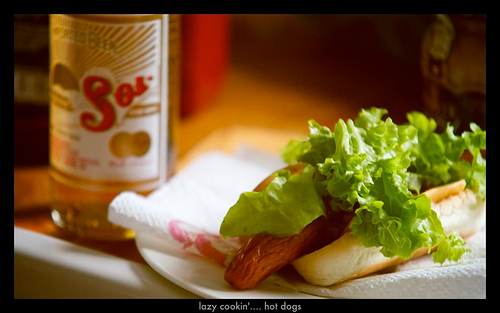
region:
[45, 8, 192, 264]
bottle made of glass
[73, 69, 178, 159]
red letters on bottle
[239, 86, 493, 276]
lettuce on the top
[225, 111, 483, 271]
the lettuce is green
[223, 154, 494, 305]
hot dog is inside bun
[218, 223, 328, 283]
hot dog is wrinkled up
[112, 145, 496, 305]
napkin under the bread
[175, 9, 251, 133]
red object behind glass bottle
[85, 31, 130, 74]
word beer is on bottle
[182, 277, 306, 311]
white letters on bottom of picture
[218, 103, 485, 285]
hot dog on a bun with lettuce on top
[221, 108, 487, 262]
green fresh lettuce on hot dog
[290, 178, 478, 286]
hot dog bun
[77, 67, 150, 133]
red symbol on on beer bottle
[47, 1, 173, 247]
bottle of beer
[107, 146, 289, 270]
white napkin under hot dog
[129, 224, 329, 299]
white plate for hot dog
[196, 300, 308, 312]
text on bottom of picture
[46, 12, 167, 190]
label on bottle of beer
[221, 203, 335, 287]
meat portion of hot dog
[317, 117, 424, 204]
The lettuce is green.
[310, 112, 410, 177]
Lettuce is on the hot dog.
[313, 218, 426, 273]
The hot dog is in a bun.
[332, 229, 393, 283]
The bun is white and brown.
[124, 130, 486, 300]
The food is on a plate.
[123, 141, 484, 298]
The plate is round.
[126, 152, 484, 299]
The plate is white.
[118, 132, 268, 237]
paper is on the plate.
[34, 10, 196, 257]
A bottle.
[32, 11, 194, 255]
The bottle is deer.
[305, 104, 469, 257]
lettuce on hot dog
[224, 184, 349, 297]
shriveled up hot dog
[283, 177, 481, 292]
short hot dog bun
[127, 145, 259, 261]
paper towel under hot dog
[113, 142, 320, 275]
dinner napkin under hot do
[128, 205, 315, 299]
solid white dinner plate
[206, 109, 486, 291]
hot dog on bun with garnish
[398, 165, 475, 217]
slice of yellow cheese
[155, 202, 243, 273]
red designs on white napkin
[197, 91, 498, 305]
hot dog with lettuce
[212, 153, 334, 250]
lettuce leaf on hot dog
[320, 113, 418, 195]
lettuce leaf on hot dog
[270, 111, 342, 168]
lettuce leaf on hot dog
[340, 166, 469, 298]
lettuce leaf on hot dog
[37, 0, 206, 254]
glass bottle full of liquid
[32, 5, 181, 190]
label on glass bottle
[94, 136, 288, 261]
peice of a paper napkin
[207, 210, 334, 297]
wrinkled hotdog sticking out of bun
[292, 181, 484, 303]
white hot dog bun